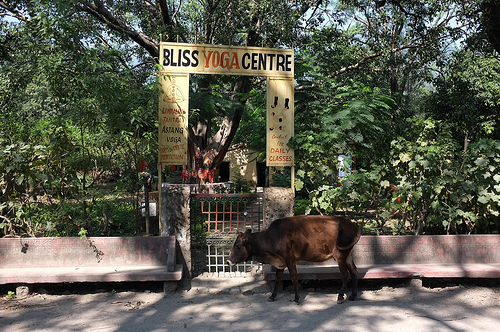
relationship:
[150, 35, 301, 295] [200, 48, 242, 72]
center of yoga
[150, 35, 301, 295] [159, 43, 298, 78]
center says bliss yoga center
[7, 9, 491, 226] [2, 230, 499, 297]
trees back of benches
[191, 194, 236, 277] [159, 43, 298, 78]
fence in front yoga center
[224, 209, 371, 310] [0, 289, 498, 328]
cow standing on ground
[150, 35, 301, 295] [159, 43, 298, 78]
centre sign says bliss yoga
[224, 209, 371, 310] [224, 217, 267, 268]
animal has side view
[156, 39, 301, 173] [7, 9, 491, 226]
sign in foreground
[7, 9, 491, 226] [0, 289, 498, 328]
trees casting shadow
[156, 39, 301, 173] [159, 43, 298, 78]
sign says bliss yoga centre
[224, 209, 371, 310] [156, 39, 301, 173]
animal standing front of sign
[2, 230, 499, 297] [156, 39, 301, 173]
benches next to sign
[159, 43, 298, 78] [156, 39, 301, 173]
words say bliss yoga centre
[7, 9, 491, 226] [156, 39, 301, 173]
trees behind sign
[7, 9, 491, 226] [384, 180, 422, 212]
trees has red ojects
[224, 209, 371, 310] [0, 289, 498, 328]
cow standing in road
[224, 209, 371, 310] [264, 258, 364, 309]
cow has four legs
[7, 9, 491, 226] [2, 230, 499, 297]
trees behind bench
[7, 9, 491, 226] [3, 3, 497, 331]
picture of day time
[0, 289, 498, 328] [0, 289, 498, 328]
shadows on ground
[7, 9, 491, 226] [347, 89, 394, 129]
trees have leaves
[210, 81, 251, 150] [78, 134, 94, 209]
trunk made of wood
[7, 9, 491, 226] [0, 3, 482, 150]
trees in background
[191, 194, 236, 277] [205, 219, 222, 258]
door made of metal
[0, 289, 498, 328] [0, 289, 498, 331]
shadow falls on ground